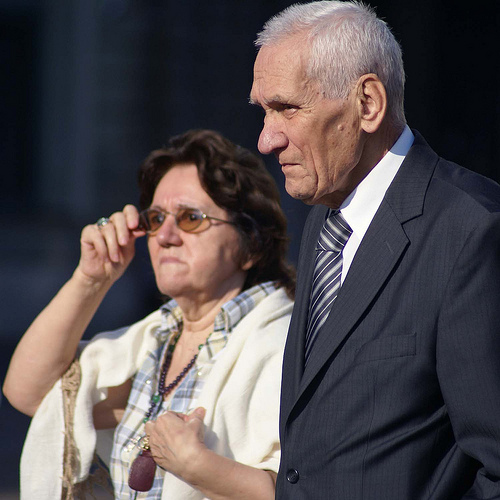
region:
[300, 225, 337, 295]
Man wearing striped tie.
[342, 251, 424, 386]
Man wearing dark suit.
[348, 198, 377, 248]
Man wearing white shirt.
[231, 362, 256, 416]
Woman wearing white wrap.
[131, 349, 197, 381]
Woman wearing necklace around neck.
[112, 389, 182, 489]
Woman wearing plaid shirt.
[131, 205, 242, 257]
Glasses on woman's face.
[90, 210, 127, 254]
Silver ring on woman's finger.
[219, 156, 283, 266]
Woman has dark hair.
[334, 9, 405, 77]
Man has gray hair.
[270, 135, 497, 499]
Man is wearing a blazer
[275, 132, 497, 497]
Man is wearing a dark blazer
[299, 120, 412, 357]
Man is wearing a shirt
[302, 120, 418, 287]
Man is wearing a white shirt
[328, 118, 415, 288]
Man is wearing a dress shirt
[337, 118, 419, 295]
Man is wearing a white dress shirt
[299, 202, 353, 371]
Man is wearing a tie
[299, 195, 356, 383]
Man is wearing a black and gray tie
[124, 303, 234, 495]
Woman is wearing a necklace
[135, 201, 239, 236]
Woman is wearing glasses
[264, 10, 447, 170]
man has grey hair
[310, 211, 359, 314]
man has striped tie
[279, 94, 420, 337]
man has white shirt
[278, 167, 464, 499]
man has blue jacket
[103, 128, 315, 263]
woman has brown hair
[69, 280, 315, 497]
woman has white jacket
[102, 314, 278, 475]
woman has striped shirt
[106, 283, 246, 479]
shirt is blue and white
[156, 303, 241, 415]
woman is wearing necklace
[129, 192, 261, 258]
woman wears dark glasses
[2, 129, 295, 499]
An elderly woman wearing sunglasses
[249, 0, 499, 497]
An elderly man looking at something intently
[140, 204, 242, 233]
Dark glasses the woman is wearing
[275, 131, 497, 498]
The grey coat the man is wearing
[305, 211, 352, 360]
The grey tie with white stripes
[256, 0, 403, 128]
White hair on the man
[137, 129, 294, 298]
Dark hair of the woman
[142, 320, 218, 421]
Necklace the woman is wearing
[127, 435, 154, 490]
Keychain in woman's left hand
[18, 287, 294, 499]
White shawl wrapped around the woman's shoulders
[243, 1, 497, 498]
Man wearing a suit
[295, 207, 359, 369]
The tie is striped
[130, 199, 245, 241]
Glasses over woman's eyes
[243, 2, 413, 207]
White hair on man's head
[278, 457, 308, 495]
A button on a jacket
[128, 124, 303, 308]
Woman has brown hair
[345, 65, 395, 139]
An ear on man's head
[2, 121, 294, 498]
Woman wearing a white coat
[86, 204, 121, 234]
Ring around a finger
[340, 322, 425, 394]
Pocket on man's jacket